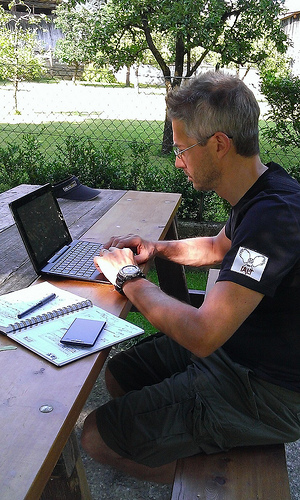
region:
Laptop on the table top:
[6, 180, 132, 289]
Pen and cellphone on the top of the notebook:
[0, 283, 118, 359]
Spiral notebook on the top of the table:
[0, 285, 133, 362]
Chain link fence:
[3, 58, 168, 149]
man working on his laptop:
[88, 54, 296, 355]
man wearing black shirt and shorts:
[98, 66, 295, 494]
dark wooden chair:
[152, 426, 293, 496]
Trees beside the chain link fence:
[66, 5, 288, 150]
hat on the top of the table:
[43, 168, 108, 201]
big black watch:
[103, 252, 151, 298]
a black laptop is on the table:
[8, 181, 128, 286]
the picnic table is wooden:
[2, 184, 292, 499]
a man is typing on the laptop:
[40, 104, 299, 351]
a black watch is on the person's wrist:
[111, 261, 144, 302]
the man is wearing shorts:
[97, 331, 298, 462]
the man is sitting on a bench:
[154, 66, 286, 496]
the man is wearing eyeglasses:
[166, 127, 223, 175]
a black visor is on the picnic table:
[48, 173, 101, 207]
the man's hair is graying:
[162, 69, 267, 213]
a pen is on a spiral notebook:
[12, 287, 66, 352]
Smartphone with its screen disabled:
[59, 315, 106, 347]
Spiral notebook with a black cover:
[0, 280, 144, 369]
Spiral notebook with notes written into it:
[1, 279, 146, 369]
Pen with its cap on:
[16, 292, 55, 319]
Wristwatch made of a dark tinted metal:
[114, 263, 145, 295]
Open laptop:
[7, 182, 121, 285]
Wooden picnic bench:
[0, 181, 289, 498]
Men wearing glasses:
[80, 70, 297, 486]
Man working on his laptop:
[8, 70, 299, 483]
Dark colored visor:
[43, 172, 100, 201]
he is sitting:
[235, 392, 294, 462]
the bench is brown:
[213, 467, 254, 492]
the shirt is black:
[250, 206, 279, 235]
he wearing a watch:
[112, 262, 144, 280]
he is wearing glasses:
[166, 143, 192, 160]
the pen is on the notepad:
[12, 293, 65, 320]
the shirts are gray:
[191, 381, 227, 408]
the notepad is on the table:
[40, 349, 65, 374]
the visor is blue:
[67, 183, 87, 195]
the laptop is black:
[72, 249, 101, 278]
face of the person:
[147, 79, 265, 192]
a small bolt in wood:
[29, 397, 63, 417]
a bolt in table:
[24, 403, 66, 421]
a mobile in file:
[58, 316, 117, 350]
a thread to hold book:
[4, 298, 101, 329]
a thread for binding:
[9, 296, 95, 333]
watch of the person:
[115, 260, 149, 281]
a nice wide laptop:
[13, 178, 122, 294]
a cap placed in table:
[38, 172, 124, 209]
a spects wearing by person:
[165, 133, 198, 157]